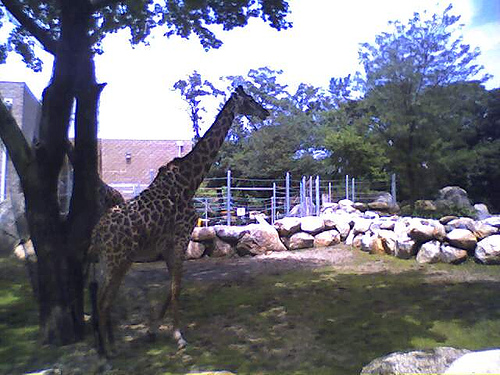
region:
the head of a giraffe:
[236, 80, 272, 121]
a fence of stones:
[313, 199, 477, 259]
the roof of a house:
[115, 135, 170, 172]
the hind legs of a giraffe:
[88, 269, 115, 365]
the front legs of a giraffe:
[155, 251, 200, 351]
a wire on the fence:
[235, 174, 285, 188]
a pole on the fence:
[223, 170, 233, 224]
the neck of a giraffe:
[187, 130, 245, 163]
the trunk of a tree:
[11, 159, 88, 335]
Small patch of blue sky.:
[473, 1, 495, 30]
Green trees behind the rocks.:
[396, 12, 478, 202]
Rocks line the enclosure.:
[292, 205, 490, 252]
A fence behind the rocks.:
[215, 168, 406, 225]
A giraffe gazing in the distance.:
[75, 65, 285, 342]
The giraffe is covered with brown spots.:
[161, 82, 273, 219]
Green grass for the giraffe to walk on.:
[296, 279, 443, 337]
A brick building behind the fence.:
[103, 119, 185, 189]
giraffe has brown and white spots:
[59, 58, 298, 366]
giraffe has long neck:
[161, 68, 286, 208]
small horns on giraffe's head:
[229, 78, 246, 95]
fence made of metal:
[218, 165, 409, 242]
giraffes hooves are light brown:
[82, 322, 205, 368]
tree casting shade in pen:
[12, 61, 497, 371]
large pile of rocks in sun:
[240, 170, 496, 275]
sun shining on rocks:
[242, 175, 499, 287]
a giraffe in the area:
[13, 9, 474, 373]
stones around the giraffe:
[250, 188, 447, 259]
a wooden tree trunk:
[2, 41, 93, 351]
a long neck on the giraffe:
[164, 85, 276, 200]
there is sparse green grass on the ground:
[236, 255, 446, 340]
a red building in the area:
[104, 125, 194, 185]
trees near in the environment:
[265, 86, 452, 163]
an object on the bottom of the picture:
[351, 337, 494, 367]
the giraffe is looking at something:
[201, 71, 490, 171]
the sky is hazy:
[113, 24, 378, 69]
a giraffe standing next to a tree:
[83, 83, 275, 365]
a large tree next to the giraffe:
[1, 2, 292, 346]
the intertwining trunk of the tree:
[0, 35, 107, 351]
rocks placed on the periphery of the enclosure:
[175, 195, 498, 276]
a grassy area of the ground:
[0, 275, 495, 370]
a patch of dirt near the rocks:
[132, 244, 349, 286]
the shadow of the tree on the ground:
[0, 254, 497, 374]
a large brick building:
[0, 78, 205, 230]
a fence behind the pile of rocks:
[122, 170, 399, 224]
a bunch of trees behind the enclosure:
[177, 5, 499, 210]